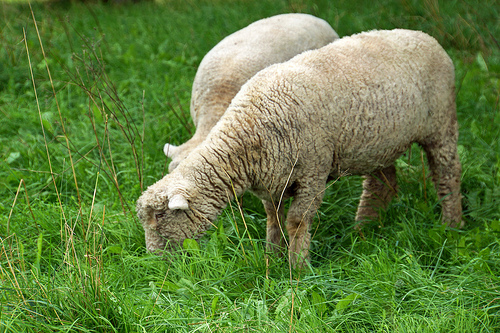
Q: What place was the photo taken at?
A: It was taken at the field.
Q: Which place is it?
A: It is a field.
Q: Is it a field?
A: Yes, it is a field.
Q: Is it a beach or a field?
A: It is a field.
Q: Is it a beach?
A: No, it is a field.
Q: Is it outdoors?
A: Yes, it is outdoors.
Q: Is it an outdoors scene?
A: Yes, it is outdoors.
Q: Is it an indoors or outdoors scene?
A: It is outdoors.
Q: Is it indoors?
A: No, it is outdoors.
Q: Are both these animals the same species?
A: Yes, all the animals are sheep.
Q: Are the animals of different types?
A: No, all the animals are sheep.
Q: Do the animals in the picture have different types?
A: No, all the animals are sheep.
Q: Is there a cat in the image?
A: No, there are no cats.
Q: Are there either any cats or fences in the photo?
A: No, there are no cats or fences.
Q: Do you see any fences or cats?
A: No, there are no cats or fences.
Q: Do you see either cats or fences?
A: No, there are no cats or fences.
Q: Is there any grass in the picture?
A: Yes, there is grass.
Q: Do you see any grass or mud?
A: Yes, there is grass.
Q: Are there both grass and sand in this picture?
A: No, there is grass but no sand.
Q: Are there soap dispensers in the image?
A: No, there are no soap dispensers.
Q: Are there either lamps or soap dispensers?
A: No, there are no soap dispensers or lamps.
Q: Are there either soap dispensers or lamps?
A: No, there are no soap dispensers or lamps.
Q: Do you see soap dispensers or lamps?
A: No, there are no soap dispensers or lamps.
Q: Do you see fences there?
A: No, there are no fences.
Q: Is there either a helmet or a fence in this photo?
A: No, there are no fences or helmets.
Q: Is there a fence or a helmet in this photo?
A: No, there are no fences or helmets.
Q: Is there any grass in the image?
A: Yes, there is grass.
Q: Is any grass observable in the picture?
A: Yes, there is grass.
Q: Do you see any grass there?
A: Yes, there is grass.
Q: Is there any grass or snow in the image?
A: Yes, there is grass.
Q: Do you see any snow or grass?
A: Yes, there is grass.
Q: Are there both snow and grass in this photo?
A: No, there is grass but no snow.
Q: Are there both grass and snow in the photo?
A: No, there is grass but no snow.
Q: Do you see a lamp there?
A: No, there are no lamps.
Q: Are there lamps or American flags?
A: No, there are no lamps or American flags.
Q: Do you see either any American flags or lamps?
A: No, there are no lamps or American flags.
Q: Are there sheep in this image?
A: Yes, there is a sheep.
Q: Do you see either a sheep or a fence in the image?
A: Yes, there is a sheep.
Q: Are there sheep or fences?
A: Yes, there is a sheep.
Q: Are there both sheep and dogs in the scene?
A: No, there is a sheep but no dogs.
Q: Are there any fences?
A: No, there are no fences.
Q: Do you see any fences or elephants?
A: No, there are no fences or elephants.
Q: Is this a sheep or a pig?
A: This is a sheep.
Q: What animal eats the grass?
A: The sheep eats the grass.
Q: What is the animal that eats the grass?
A: The animal is a sheep.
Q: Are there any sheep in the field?
A: Yes, there is a sheep in the field.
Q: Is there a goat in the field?
A: No, there is a sheep in the field.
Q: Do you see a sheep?
A: Yes, there is a sheep.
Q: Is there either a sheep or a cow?
A: Yes, there is a sheep.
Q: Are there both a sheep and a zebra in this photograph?
A: No, there is a sheep but no zebras.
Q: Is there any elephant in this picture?
A: No, there are no elephants.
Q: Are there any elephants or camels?
A: No, there are no elephants or camels.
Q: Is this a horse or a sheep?
A: This is a sheep.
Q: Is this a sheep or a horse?
A: This is a sheep.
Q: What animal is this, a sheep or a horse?
A: This is a sheep.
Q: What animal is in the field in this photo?
A: The animal is a sheep.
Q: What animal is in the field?
A: The animal is a sheep.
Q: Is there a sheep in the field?
A: Yes, there is a sheep in the field.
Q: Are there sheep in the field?
A: Yes, there is a sheep in the field.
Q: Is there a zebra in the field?
A: No, there is a sheep in the field.